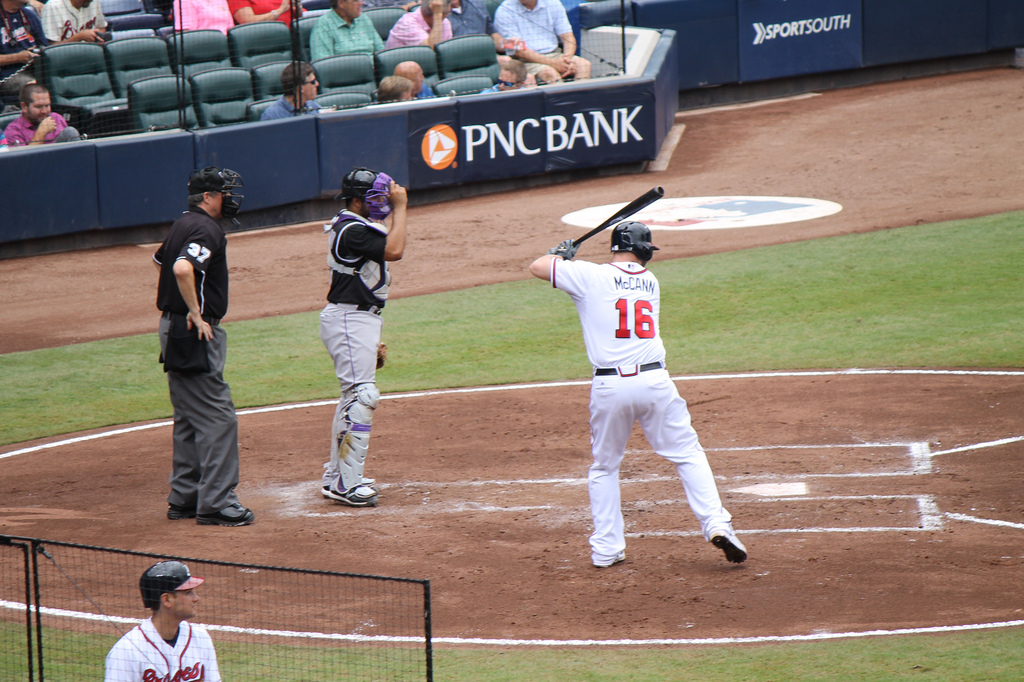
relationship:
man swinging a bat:
[523, 214, 772, 578] [532, 154, 656, 265]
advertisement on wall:
[397, 81, 666, 188] [6, 130, 698, 232]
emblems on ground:
[540, 171, 849, 252] [335, 145, 992, 321]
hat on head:
[136, 545, 212, 598] [115, 536, 209, 619]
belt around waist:
[586, 359, 680, 385] [586, 338, 677, 393]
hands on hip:
[166, 305, 216, 345] [153, 282, 231, 371]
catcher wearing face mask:
[297, 155, 404, 521] [357, 175, 407, 215]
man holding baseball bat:
[519, 179, 785, 599] [528, 179, 682, 275]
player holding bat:
[535, 165, 806, 596] [550, 158, 667, 265]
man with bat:
[517, 247, 744, 548] [573, 150, 682, 267]